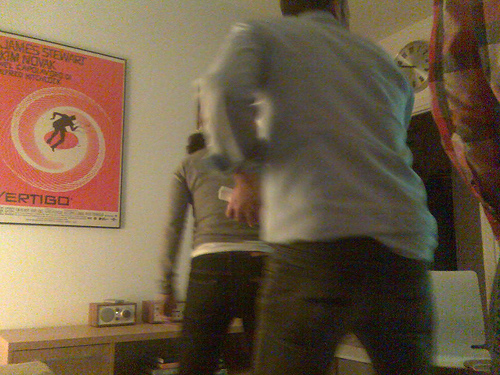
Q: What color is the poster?
A: Red.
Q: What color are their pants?
A: Black.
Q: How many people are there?
A: Two.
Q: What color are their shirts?
A: Gray.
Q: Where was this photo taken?
A: In the living room.